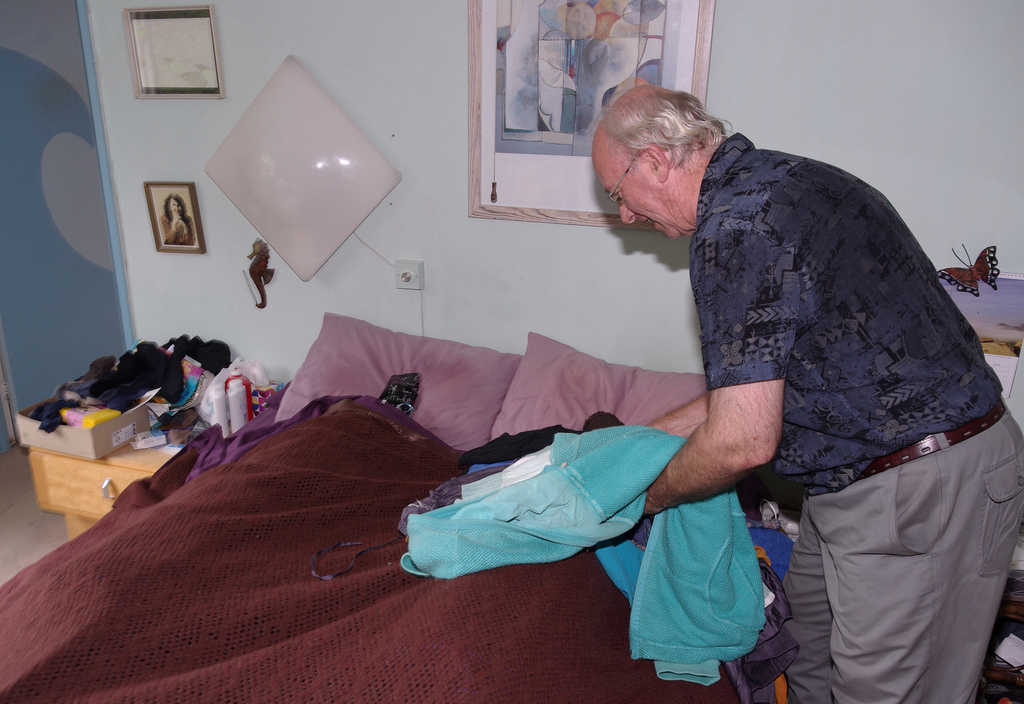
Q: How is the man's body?
A: Bent over.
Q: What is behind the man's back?
A: Butterfly.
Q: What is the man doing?
A: Sorting laundry.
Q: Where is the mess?
A: On the nightstand.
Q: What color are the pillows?
A: Pink.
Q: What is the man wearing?
A: Blue shirt and khaki slacks.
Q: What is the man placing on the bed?
A: Laundry.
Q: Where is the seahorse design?
A: On the wall.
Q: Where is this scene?
A: In the bedroom.